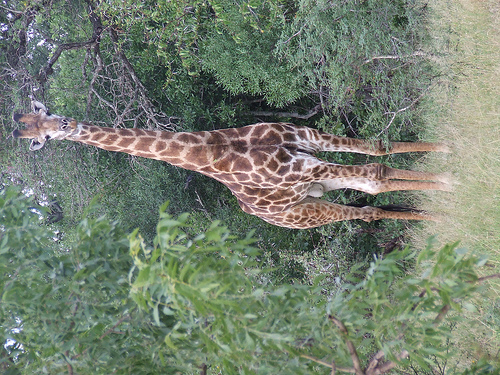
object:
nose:
[55, 116, 70, 131]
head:
[13, 100, 80, 154]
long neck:
[78, 122, 209, 172]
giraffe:
[10, 99, 455, 232]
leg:
[314, 200, 409, 223]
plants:
[114, 0, 500, 375]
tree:
[3, 1, 433, 204]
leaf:
[173, 26, 220, 72]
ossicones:
[7, 107, 33, 142]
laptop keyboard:
[10, 102, 26, 150]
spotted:
[257, 122, 378, 180]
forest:
[3, 0, 499, 375]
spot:
[211, 151, 232, 174]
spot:
[245, 146, 279, 169]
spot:
[230, 136, 249, 157]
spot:
[216, 126, 249, 141]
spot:
[187, 146, 208, 167]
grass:
[384, 0, 499, 374]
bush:
[126, 199, 500, 374]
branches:
[0, 0, 184, 212]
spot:
[132, 137, 156, 151]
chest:
[230, 118, 295, 194]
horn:
[10, 112, 33, 122]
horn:
[12, 124, 31, 138]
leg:
[321, 130, 431, 156]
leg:
[324, 161, 411, 181]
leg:
[347, 180, 407, 194]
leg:
[332, 202, 421, 228]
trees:
[0, 183, 499, 375]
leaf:
[194, 258, 244, 297]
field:
[0, 0, 499, 375]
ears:
[23, 96, 49, 154]